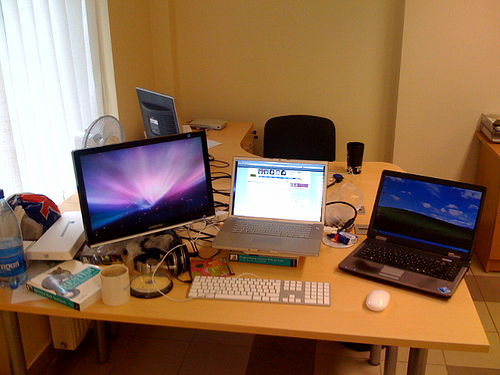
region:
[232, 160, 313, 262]
Silver laptop on top of desk.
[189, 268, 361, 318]
White buttons on keyboard.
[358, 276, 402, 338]
White wireless computer mouse on desk.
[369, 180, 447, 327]
Black and silver laptop on desk.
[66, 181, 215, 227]
Black desktop on desk.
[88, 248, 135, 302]
White coffee mug on desk.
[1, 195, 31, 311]
Bottle of water on desk.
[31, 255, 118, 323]
Cat on cover of book on desk.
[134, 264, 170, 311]
Disks in case on top of desk.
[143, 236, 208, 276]
Headphones sitting on top of desk.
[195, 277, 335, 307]
white keyboard with keys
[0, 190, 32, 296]
clear plastic bottle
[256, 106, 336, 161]
black desk chair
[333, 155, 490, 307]
black laptop with screen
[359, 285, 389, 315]
white computer mouse on the table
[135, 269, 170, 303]
yellow cds on the table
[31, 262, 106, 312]
book with a cat on it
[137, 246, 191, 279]
black and silver headphones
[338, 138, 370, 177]
black cup with prints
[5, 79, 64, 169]
sheer white curtains on the window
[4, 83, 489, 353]
Work space is cluttered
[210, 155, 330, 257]
Silver laptop open and running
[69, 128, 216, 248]
Desktop monitor displays background image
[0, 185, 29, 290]
Water bottle sits near computers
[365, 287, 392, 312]
Small, white wireless mouse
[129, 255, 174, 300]
Mostly empty CD stack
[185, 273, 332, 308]
Wireless keyboard connects to laptop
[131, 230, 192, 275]
Headphones tucked under monitor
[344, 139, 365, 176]
Generic, black plastic cup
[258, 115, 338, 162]
Black office chair is empty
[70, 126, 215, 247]
the monitor is on a desk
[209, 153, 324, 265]
the laptop is on a desk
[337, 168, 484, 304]
the laptop is on a desk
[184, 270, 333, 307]
the keyboard is in from of the laptop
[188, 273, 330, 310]
the keyboard is on the desk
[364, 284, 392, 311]
the mouse is on the desk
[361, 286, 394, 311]
the mouse is white in color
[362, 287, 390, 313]
the mouse is corless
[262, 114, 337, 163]
the chair is behind the desk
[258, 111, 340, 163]
the chair is black in color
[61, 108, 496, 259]
The screens are all on.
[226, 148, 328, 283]
This is an apple computer.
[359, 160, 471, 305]
This is a window computer.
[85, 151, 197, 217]
The screensave is purple and blue.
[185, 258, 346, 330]
The keyboard is silver.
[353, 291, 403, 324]
This mouse is wireless.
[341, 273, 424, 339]
This mouse is white.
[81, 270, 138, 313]
This is a coffee mug.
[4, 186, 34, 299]
This is a water bottle.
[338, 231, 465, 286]
This computer is dark gray.